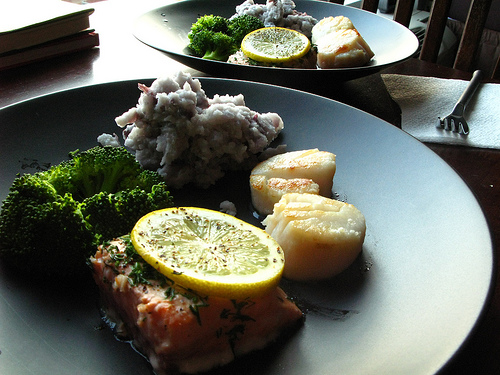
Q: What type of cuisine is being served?
A: Seafood.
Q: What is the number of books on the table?
A: Two.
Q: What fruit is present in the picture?
A: Lemon.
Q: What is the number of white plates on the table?
A: Two.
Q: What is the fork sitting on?
A: A napkin.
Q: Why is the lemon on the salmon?
A: For flavor.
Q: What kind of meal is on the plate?
A: Dinner.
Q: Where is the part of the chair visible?
A: In the top right corner.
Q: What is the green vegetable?
A: Broccoli.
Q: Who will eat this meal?
A: Two people.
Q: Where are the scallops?
A: Next to the fish.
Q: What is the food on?
A: A table.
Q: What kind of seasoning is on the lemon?
A: Black pepper.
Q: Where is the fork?
A: On the right.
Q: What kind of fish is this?
A: Salmon.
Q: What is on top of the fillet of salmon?
A: A slice of lemon.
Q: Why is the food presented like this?
A: To make it appealing to the person who will eat it.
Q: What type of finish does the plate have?
A: A matte finish.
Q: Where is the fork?
A: On top of the white napkin.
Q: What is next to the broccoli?
A: Mashed potatoes.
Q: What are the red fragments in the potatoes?
A: Potato skins.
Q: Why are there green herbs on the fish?
A: To garnish and flavor it.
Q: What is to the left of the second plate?
A: A book.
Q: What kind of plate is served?
A: Seafood.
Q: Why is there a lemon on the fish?
A: For flavor.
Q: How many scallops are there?
A: Two.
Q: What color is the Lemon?
A: Yellow.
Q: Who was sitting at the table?
A: No one.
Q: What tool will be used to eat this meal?
A: A fork.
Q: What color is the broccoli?
A: Green.